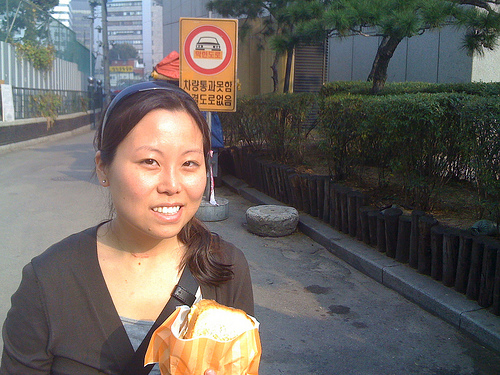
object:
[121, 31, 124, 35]
window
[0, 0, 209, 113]
building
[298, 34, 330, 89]
shutter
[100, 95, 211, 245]
face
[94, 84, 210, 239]
head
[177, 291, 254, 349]
sandwich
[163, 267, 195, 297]
strap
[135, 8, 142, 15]
window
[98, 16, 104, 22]
window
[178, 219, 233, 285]
pony tail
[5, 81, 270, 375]
girl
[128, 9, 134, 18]
window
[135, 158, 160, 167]
eye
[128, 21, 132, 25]
window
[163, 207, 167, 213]
teeth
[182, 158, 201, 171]
left eye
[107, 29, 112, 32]
window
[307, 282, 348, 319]
shadow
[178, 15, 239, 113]
sign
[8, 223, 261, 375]
shirt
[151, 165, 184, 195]
nose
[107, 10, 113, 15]
window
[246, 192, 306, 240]
stonebase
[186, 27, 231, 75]
circle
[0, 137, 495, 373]
ground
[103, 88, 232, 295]
hair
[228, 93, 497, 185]
hedge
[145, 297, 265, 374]
bag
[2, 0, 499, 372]
city